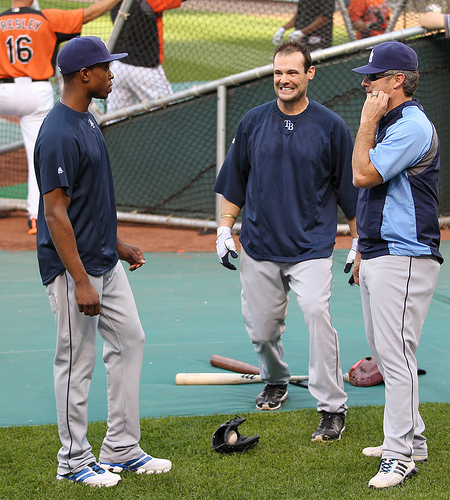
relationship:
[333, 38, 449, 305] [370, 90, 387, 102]
man wearing ring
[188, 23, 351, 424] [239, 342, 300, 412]
man has foot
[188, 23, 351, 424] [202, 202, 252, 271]
man has hand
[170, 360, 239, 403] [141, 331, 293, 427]
bat on ground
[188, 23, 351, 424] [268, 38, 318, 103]
man with face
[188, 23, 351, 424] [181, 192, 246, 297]
man has hand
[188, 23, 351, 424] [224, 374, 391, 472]
man on field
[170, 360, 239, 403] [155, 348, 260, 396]
bat on floor